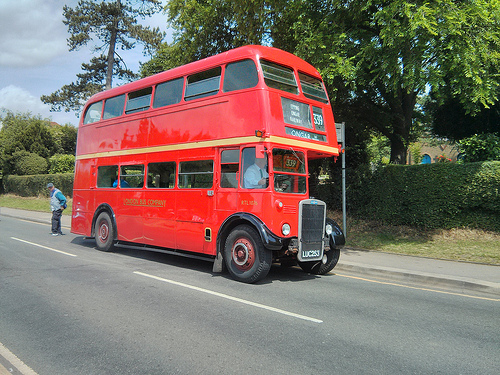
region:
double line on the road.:
[6, 348, 18, 373]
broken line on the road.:
[273, 300, 328, 324]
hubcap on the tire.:
[234, 242, 250, 263]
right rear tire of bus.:
[94, 212, 110, 245]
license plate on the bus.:
[297, 249, 319, 265]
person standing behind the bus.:
[46, 180, 67, 227]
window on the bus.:
[230, 67, 251, 83]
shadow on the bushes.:
[393, 183, 453, 220]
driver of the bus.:
[249, 160, 266, 191]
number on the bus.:
[310, 110, 320, 130]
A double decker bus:
[74, 32, 362, 271]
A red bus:
[66, 43, 368, 290]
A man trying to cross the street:
[26, 167, 71, 270]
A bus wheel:
[204, 210, 282, 297]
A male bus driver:
[216, 130, 287, 205]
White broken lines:
[7, 232, 336, 351]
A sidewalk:
[351, 234, 498, 308]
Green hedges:
[366, 145, 499, 247]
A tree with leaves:
[331, 3, 495, 155]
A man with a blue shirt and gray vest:
[36, 176, 71, 246]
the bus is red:
[61, 39, 353, 289]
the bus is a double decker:
[63, 43, 365, 283]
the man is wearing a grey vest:
[49, 186, 66, 215]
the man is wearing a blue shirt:
[47, 189, 68, 211]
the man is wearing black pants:
[48, 206, 65, 235]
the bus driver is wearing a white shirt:
[242, 162, 276, 194]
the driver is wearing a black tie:
[257, 167, 267, 182]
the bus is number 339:
[311, 108, 326, 128]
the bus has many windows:
[80, 52, 334, 197]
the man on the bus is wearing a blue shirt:
[110, 179, 128, 189]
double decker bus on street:
[63, 42, 361, 281]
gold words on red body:
[116, 193, 202, 239]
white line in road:
[129, 267, 328, 329]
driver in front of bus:
[240, 149, 269, 198]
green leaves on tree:
[377, 11, 462, 58]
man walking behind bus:
[43, 172, 76, 241]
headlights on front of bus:
[275, 220, 336, 241]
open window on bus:
[177, 60, 226, 101]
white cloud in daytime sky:
[7, 74, 38, 109]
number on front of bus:
[303, 110, 330, 132]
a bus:
[67, 44, 349, 289]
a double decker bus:
[66, 43, 346, 285]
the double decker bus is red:
[65, 43, 345, 283]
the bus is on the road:
[70, 44, 362, 291]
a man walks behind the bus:
[39, 177, 70, 236]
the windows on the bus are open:
[66, 46, 355, 283]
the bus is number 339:
[67, 41, 355, 282]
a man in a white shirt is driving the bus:
[237, 143, 298, 197]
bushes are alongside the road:
[9, 161, 489, 233]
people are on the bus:
[71, 44, 365, 289]